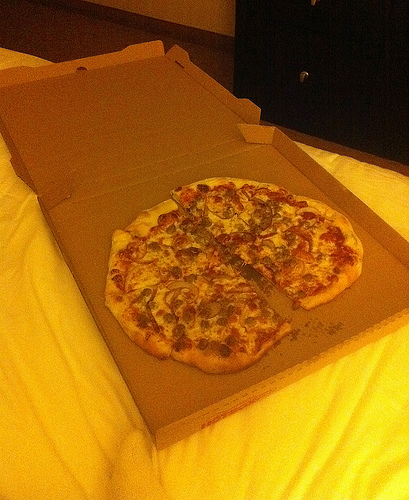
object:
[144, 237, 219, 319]
cheese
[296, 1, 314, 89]
knobs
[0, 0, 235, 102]
flooring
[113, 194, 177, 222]
crust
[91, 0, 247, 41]
base trim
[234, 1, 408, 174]
dresser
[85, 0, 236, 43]
wall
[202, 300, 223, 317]
mushroom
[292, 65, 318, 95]
knob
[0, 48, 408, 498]
sheet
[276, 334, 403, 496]
creases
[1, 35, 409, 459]
pizza box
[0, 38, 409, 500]
bed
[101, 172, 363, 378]
pizza